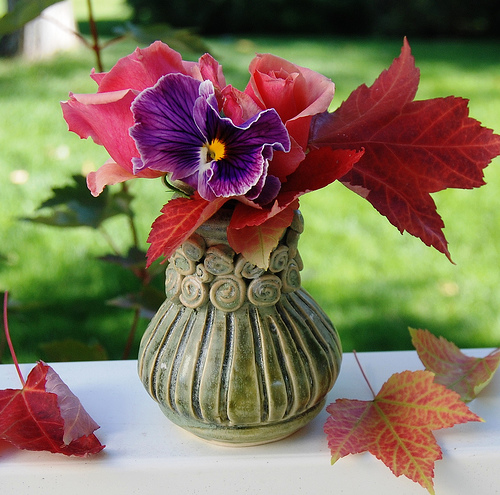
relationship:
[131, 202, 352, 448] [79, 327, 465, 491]
vase on table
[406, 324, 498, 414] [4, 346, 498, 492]
leaf on table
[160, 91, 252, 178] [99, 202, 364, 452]
flower in vase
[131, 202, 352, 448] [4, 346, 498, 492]
vase on table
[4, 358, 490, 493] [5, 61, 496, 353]
table in yard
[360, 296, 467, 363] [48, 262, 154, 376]
shadow on grass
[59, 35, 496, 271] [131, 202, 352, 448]
flowers in vase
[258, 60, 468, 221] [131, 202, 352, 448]
leaves in vase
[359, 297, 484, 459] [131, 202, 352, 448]
leaves next vase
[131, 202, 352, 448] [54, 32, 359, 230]
vase holding flowers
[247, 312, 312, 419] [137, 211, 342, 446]
groove on vase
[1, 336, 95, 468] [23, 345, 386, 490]
leaf on table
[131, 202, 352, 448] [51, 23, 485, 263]
vase with flowers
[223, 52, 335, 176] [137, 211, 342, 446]
rose in vase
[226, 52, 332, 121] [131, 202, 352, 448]
pink rose in vase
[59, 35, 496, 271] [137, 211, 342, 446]
flowers in vase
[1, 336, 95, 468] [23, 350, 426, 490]
leaf on a table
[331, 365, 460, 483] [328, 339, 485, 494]
veins of a leaf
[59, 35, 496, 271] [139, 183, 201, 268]
flowers and leaves